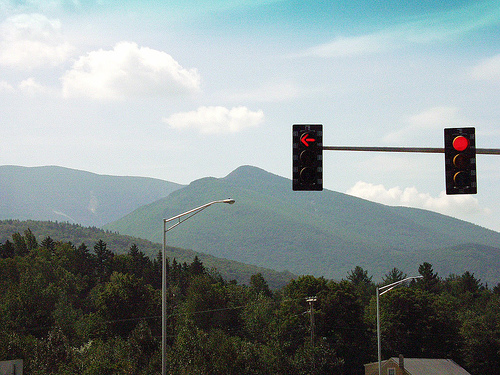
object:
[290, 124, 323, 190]
light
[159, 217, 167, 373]
pole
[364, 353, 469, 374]
house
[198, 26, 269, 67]
sky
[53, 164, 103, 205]
mountian